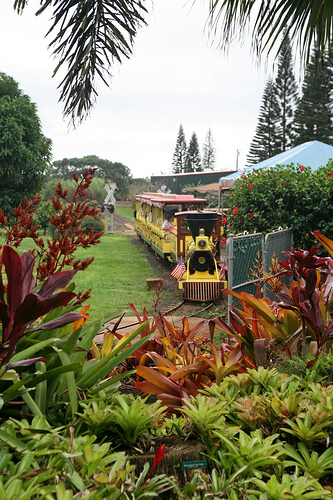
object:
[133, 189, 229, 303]
train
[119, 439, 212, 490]
tree stump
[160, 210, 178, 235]
tourists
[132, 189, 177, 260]
side of train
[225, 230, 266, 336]
metal gate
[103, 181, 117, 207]
crossing sign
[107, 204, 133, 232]
tracks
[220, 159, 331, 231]
tree top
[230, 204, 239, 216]
red flowers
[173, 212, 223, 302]
front of train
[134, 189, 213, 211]
roof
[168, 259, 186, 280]
american flag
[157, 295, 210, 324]
part of track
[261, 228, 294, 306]
chain link gate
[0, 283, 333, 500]
green plants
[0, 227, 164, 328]
grass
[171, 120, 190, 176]
trees in the distanc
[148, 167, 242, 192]
building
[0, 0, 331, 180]
sky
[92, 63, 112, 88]
palm frond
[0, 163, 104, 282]
plant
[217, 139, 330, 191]
awning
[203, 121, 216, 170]
evergreen trees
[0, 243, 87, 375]
plant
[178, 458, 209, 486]
sign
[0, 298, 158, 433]
plant